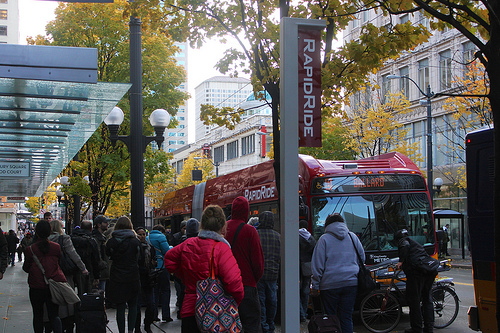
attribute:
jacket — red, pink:
[163, 236, 245, 315]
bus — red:
[138, 110, 447, 324]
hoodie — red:
[217, 190, 269, 289]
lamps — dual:
[105, 105, 176, 154]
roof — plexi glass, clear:
[3, 42, 137, 201]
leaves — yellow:
[31, 0, 492, 212]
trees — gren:
[21, 2, 499, 276]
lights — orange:
[317, 165, 425, 181]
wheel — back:
[360, 285, 403, 327]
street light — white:
[105, 104, 129, 152]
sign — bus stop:
[294, 26, 329, 145]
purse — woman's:
[192, 240, 249, 333]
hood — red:
[230, 196, 249, 221]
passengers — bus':
[22, 185, 456, 331]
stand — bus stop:
[3, 45, 137, 319]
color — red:
[300, 33, 318, 143]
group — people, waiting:
[16, 190, 444, 324]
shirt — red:
[19, 241, 64, 289]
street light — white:
[146, 107, 177, 150]